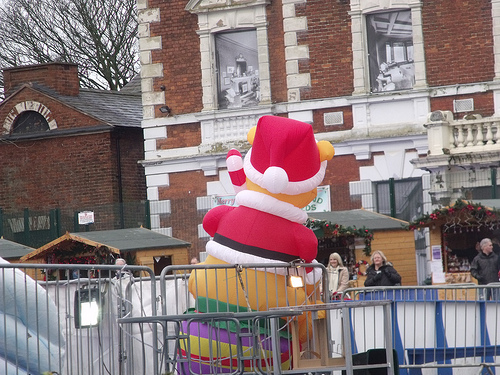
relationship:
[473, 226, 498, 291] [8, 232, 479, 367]
man on street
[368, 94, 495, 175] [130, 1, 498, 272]
balcony on front of building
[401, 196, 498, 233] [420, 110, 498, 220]
holly lights on store front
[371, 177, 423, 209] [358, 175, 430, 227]
bars over window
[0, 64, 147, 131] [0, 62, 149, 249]
roof of building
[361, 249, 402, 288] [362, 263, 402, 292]
woman wearing jacket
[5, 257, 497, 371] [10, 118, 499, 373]
fencing at christmas display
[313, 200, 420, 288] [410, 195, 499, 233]
shed with christmas decorations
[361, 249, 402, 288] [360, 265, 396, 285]
woman wearing jacket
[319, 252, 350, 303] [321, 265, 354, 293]
woman wearing tan jacket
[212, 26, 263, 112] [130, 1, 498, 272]
window on building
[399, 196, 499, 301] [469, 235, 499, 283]
booth with vendor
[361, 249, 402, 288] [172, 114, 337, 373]
woman viewing christmas display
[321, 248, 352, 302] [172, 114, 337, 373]
woman viewing christmas display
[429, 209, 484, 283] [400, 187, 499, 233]
booth with christmas decorations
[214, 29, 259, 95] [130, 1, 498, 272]
window in building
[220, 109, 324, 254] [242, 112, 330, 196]
bear wearing hat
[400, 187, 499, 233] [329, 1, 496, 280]
christmas decorations are on building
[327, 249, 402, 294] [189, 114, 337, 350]
couple watching bear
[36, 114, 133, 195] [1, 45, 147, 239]
bricks are on building